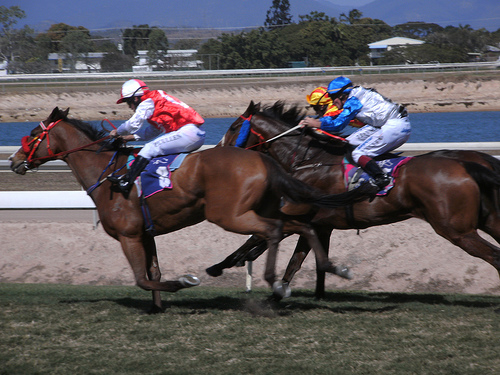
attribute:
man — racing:
[7, 71, 355, 318]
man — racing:
[206, 71, 498, 289]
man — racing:
[205, 79, 500, 312]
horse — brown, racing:
[7, 103, 357, 320]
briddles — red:
[19, 112, 131, 173]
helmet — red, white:
[114, 75, 152, 107]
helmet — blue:
[326, 71, 360, 99]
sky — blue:
[6, 1, 499, 32]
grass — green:
[1, 279, 485, 370]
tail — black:
[259, 151, 385, 209]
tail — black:
[461, 154, 500, 199]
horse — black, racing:
[203, 97, 498, 294]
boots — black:
[107, 152, 158, 199]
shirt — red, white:
[110, 89, 212, 153]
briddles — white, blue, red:
[212, 105, 323, 155]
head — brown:
[7, 102, 74, 178]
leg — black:
[204, 233, 259, 280]